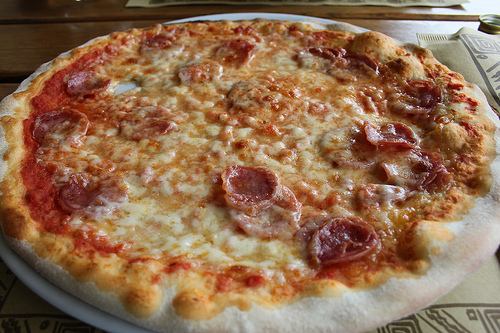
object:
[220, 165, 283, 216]
pepperoni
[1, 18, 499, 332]
pizza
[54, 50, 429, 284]
melted cheese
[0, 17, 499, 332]
crust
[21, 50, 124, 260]
sauce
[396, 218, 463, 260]
air pocket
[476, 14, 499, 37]
bottle cap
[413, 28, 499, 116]
napkin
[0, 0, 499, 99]
table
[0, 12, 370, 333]
plate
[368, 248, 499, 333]
box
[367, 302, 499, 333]
design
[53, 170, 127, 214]
ham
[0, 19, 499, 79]
slats